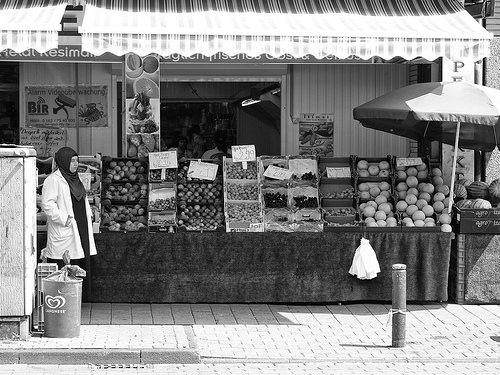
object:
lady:
[39, 146, 96, 301]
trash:
[40, 275, 83, 341]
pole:
[443, 122, 460, 214]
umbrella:
[351, 79, 498, 152]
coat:
[41, 170, 96, 262]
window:
[159, 66, 283, 157]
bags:
[345, 234, 381, 281]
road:
[7, 358, 499, 375]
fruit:
[290, 195, 317, 211]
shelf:
[91, 230, 451, 303]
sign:
[22, 83, 108, 130]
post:
[387, 262, 407, 349]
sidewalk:
[3, 301, 498, 355]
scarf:
[53, 144, 85, 202]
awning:
[74, 1, 494, 64]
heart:
[44, 294, 67, 310]